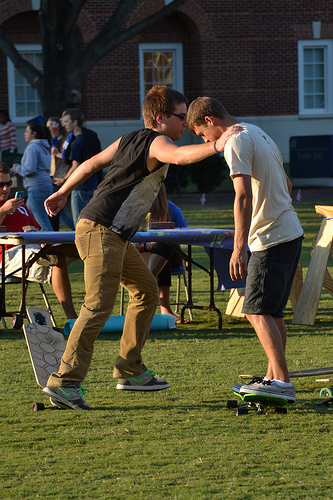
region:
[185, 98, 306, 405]
Man wearing a white shirt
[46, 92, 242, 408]
Man wearing brown pants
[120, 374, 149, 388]
Green nike logo on shoe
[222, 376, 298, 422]
Skateboard under man's feet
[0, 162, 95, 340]
Man wearing a red shirt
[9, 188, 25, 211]
Cellphone in man's hand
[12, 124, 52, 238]
Woman wearing gray hoodie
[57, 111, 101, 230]
Man wearing a blue shirt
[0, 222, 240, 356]
Folding table on grass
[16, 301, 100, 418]
Skateboard under boy's foot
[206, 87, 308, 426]
a boy on a skateboard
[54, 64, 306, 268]
a boy touching another boy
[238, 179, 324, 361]
a boy with shorts on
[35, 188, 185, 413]
a boy with brown pants on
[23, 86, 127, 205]
people in front of a tree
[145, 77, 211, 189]
boy with glasses on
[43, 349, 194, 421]
boy with nike shoes on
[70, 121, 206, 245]
boy with a black shirt on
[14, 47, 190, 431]
boy falling off skateboard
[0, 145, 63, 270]
a man looking at his cell phone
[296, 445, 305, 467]
part of a lawn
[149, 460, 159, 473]
part of a field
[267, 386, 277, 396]
part of a shoe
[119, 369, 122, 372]
part of a trouser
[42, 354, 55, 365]
edge of a board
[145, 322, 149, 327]
part of a trouser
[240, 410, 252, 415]
part of a wheel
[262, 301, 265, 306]
part of a short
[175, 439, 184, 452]
part of a garden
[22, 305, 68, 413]
skate board being tipped over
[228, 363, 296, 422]
feet on the top of skate board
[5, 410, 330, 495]
grass field in green color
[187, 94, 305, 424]
a kid is on the skate board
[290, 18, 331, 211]
glass window with wooden frame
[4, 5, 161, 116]
a tree in front of the building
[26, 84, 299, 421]
kids playing with skate board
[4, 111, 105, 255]
group of youths are walking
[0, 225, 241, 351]
a table with a cloth on top of it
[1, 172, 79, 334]
a guy with red color t-shirt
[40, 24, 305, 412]
two boys are playing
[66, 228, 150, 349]
the pant is black in colour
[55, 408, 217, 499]
the grass is green in colour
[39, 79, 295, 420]
the boys are in skates board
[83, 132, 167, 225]
the vest is black in colour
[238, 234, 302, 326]
the short is black in colour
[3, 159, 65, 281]
a person is using a phone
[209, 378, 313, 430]
the scateboard is green in colour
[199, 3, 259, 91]
the wall is brown in colour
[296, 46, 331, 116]
the window is closed